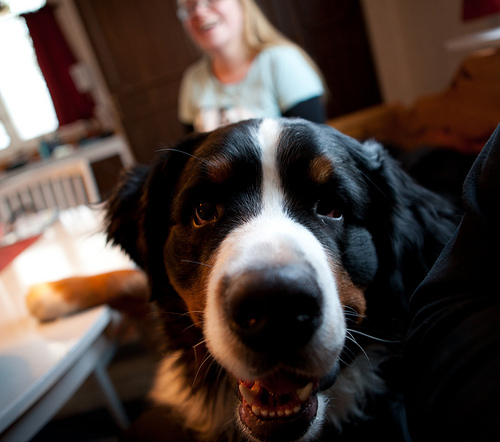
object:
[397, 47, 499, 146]
chair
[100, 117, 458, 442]
dog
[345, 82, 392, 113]
ground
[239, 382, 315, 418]
canine tooth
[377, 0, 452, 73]
wall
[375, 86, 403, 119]
ground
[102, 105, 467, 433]
mirror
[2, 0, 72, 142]
window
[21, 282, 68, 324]
paw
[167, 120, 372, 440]
face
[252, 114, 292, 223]
stripe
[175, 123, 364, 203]
forehead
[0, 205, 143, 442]
table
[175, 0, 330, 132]
lady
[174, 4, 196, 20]
glasses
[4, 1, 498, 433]
living room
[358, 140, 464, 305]
ear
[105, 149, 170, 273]
ear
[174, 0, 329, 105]
hair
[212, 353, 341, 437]
mouth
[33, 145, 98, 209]
ocean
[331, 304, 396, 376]
whiskers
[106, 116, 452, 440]
head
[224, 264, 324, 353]
nose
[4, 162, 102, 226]
chair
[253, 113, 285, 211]
line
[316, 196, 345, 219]
eye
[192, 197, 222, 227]
eye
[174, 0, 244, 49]
face